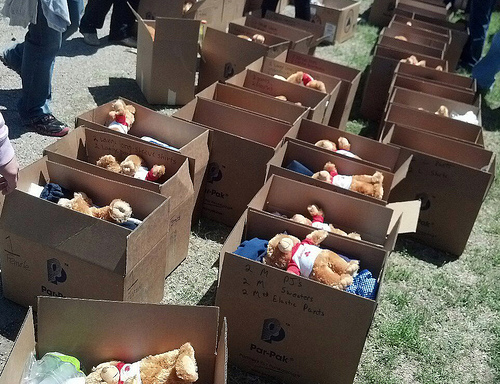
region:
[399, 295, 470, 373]
grass on the ground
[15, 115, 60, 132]
shoe on the foot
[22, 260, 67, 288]
symbol on the box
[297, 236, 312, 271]
shirt on the bear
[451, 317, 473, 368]
dry patches in grass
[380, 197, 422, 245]
flap of the box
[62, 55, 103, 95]
gravel on the ground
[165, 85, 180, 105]
tape on the box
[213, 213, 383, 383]
an open cardboard box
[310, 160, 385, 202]
teddy bear laying at the top of the box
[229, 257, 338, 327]
handwriting on the side of the box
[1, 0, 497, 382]
several cardboard boxes sitting on the grass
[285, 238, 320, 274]
red and white shirt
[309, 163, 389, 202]
bear wearing a shirt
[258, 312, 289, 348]
logo on the side of the box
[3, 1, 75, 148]
person standing on the grass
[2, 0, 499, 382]
grass on the ground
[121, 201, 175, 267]
flap on the top of the box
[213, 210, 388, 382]
Cardboard box with a teddy bear on top.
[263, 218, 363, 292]
Teddy bear on the top of a box.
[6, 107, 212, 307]
Boxes sitting in the grass.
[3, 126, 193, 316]
Packed boxes sitting in the grass.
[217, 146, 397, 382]
Boxes with teddy bears in the grass.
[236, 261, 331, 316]
Itemized list of what is in a box.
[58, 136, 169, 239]
Teddy bears packed in boxes.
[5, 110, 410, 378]
Many boxes backed with a variety of items.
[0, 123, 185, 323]
Open boxes sitting in the grass.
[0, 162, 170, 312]
Open packed box in the grass.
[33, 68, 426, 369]
lots of teddy bears kept in the cardboard box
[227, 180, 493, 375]
cardboard kept in the green grass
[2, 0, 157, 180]
many people are standing near the cardboard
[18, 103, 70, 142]
a person wearing black color shoe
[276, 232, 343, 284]
brown color teddy bear in the cardboard box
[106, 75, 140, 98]
shadow of the cardboard box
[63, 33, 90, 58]
shadow of the person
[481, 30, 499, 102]
a person wearing blue color jean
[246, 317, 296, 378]
black color text written in the cardboard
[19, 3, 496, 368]
teddy bears are in boxes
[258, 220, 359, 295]
the teddy has brown fur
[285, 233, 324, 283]
the teddy bear wears a shirt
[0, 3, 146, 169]
peoples feet can be seen behind the boxes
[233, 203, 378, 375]
the box is made of cardboard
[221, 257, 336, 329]
some writing is on the side of the box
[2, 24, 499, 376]
some grass is on the ground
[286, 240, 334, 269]
the teddy bear's shirt is red and white in color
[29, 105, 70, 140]
the mans shoe is black in color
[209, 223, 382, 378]
a cardboard box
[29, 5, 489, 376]
many cardboard boxes on the ground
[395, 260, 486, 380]
grass on the ground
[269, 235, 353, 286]
a stuffed animal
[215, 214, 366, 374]
a teddy bear in a box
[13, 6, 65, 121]
the legs of a person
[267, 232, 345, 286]
a teddy bear with a white shirt on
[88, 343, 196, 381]
brown teddy bear in box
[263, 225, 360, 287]
brown teddy bear in box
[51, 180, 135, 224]
brown teddy bear in box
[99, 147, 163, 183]
brown teddy bear in box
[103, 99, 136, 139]
brown teddy bear in box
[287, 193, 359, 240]
brown teddy bear in box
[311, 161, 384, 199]
brown teddy bear in box